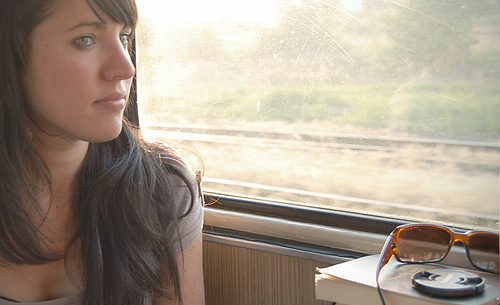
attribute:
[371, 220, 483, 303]
glasses — sun, big, brown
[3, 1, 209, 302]
woman — brunette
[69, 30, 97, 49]
eye — blue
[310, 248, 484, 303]
book — unopened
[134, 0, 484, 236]
window — scratchy, blurry, train, Large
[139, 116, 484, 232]
tracks — train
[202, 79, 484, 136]
bushes — green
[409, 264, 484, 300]
object — black, round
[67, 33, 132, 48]
eyes — open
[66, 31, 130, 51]
eyes — bluish green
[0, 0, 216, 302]
hair — long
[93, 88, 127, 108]
mouth — closed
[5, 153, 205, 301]
shirt — light brown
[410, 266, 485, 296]
lid — small, black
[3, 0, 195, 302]
hair — long, brown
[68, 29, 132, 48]
woman's eyes — green